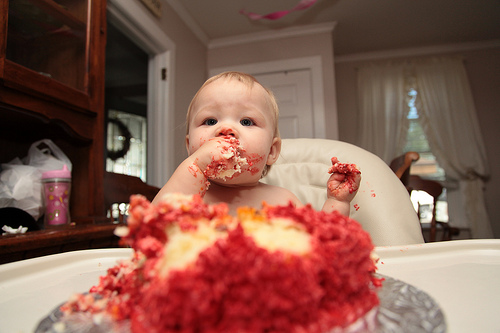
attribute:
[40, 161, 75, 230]
sippy cup — pink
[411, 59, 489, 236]
curtain — white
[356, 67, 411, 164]
curtain — white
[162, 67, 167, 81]
hinge — old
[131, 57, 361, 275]
child — eating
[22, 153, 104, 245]
cup — pink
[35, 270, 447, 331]
platter — cut glass, cake platter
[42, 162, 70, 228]
sippy cup — pink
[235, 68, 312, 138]
door — white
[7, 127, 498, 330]
chair — high chair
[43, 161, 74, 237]
bottle — pink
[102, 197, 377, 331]
cake — red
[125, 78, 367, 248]
baby — blonde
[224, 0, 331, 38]
streamer — two toned, pink